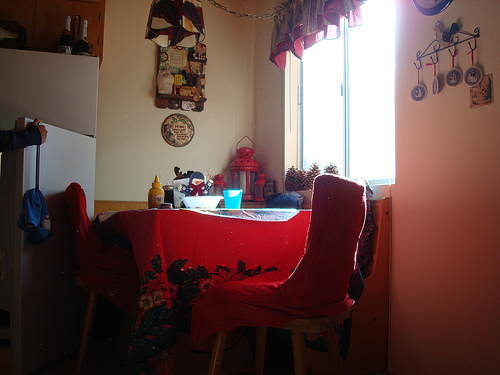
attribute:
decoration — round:
[148, 108, 205, 152]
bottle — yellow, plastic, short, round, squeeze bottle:
[148, 174, 164, 209]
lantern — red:
[227, 135, 262, 202]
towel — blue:
[9, 134, 70, 276]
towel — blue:
[17, 185, 54, 247]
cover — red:
[245, 177, 383, 321]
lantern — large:
[224, 126, 263, 206]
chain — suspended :
[206, 0, 291, 30]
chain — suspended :
[198, 0, 290, 22]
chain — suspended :
[192, 1, 307, 22]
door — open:
[12, 110, 99, 297]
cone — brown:
[284, 165, 296, 188]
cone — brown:
[295, 169, 305, 188]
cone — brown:
[304, 161, 318, 188]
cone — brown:
[325, 163, 338, 173]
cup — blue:
[221, 189, 243, 211]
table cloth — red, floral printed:
[93, 195, 313, 360]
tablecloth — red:
[95, 207, 311, 341]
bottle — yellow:
[147, 173, 164, 208]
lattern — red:
[217, 132, 273, 203]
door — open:
[0, 112, 98, 369]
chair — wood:
[187, 175, 376, 372]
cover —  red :
[308, 175, 357, 307]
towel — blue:
[16, 187, 51, 252]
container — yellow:
[148, 170, 166, 210]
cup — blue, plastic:
[220, 187, 245, 209]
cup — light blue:
[221, 187, 246, 214]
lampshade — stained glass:
[148, 5, 211, 54]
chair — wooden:
[190, 170, 353, 364]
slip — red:
[162, 170, 371, 335]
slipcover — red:
[190, 175, 366, 351]